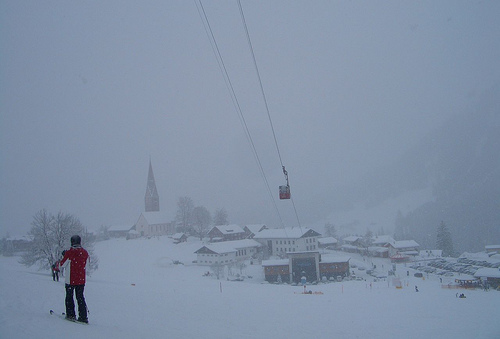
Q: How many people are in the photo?
A: 1.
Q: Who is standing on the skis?
A: The man in the red jacket.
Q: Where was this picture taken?
A: At a ski resort.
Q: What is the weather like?
A: Snowy and foggy.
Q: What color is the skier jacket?
A: Red and white.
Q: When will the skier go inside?
A: When they ski down the hill.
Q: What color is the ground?
A: White.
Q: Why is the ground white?
A: It is covered in snow.